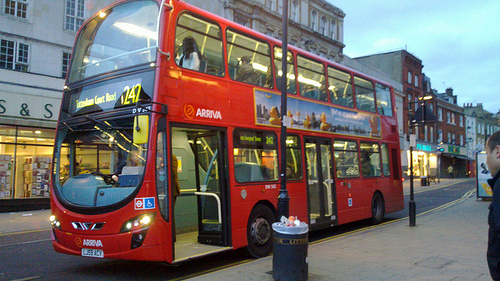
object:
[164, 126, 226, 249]
doorway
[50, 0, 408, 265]
bus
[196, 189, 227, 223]
safety handle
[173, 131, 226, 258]
door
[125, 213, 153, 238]
headlight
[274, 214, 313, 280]
trash can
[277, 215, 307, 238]
trash bag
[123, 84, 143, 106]
247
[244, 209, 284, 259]
tire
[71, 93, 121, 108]
route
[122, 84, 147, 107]
number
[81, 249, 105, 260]
tag number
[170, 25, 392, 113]
upper deck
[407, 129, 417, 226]
light post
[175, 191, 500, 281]
curb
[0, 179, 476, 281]
street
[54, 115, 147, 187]
windshield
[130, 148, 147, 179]
driver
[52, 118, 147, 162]
windshield wipers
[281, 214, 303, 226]
trash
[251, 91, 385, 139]
picture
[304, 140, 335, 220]
doors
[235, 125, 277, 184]
window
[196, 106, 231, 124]
letters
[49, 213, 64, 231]
headlight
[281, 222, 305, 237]
bag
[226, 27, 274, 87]
windows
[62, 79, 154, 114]
display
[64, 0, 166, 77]
window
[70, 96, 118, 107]
lettering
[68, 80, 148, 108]
lights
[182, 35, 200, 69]
people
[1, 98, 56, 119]
letters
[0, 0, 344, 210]
building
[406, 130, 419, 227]
street lamp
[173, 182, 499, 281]
sidewalk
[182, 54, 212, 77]
shirt